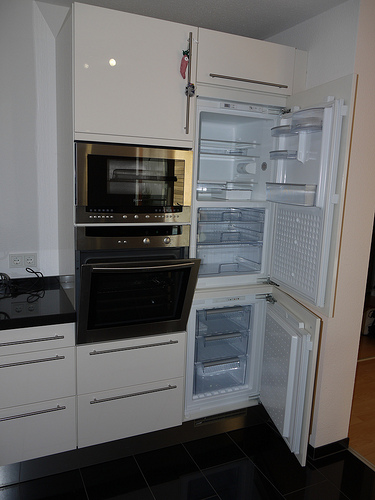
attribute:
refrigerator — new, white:
[186, 69, 362, 473]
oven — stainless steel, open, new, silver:
[71, 221, 199, 345]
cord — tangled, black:
[0, 265, 47, 307]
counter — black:
[2, 273, 77, 335]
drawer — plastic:
[197, 307, 254, 339]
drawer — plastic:
[193, 330, 251, 364]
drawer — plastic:
[195, 357, 250, 397]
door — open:
[267, 71, 362, 322]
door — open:
[254, 282, 324, 472]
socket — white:
[7, 250, 39, 271]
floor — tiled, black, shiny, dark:
[4, 416, 373, 500]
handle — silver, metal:
[92, 266, 193, 271]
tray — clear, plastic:
[263, 179, 316, 211]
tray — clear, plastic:
[267, 147, 301, 168]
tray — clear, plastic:
[266, 122, 298, 140]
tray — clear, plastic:
[293, 117, 329, 137]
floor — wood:
[323, 330, 374, 471]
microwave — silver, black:
[71, 137, 196, 228]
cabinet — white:
[65, 2, 201, 140]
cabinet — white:
[191, 25, 305, 103]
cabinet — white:
[74, 327, 190, 452]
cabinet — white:
[1, 317, 82, 470]